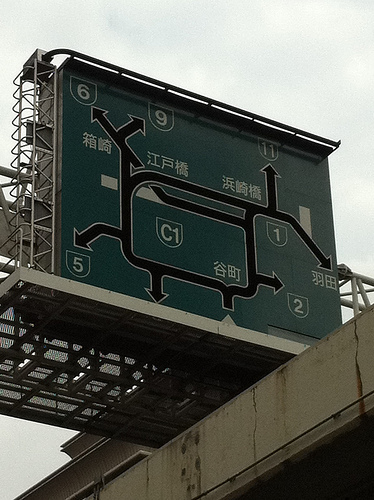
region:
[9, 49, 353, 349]
black structure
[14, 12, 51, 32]
white clouds in blue sky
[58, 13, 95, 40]
white clouds in blue sky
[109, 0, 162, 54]
white clouds in blue sky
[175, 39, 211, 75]
white clouds in blue sky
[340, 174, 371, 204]
white clouds in blue sky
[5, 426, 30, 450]
white clouds in blue sky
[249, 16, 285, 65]
white clouds in blue sky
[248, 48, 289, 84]
white clouds in blue sky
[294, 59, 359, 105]
white clouds in blue sky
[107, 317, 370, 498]
a broken top of a wall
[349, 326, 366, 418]
rust in the crack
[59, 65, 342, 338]
a green traffic sign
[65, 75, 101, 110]
the number 6 on the sign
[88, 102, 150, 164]
arrows pointing to the 6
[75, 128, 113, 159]
characters on the sign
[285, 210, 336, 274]
an arrow pointing down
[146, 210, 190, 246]
C1 on the sign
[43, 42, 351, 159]
a bar across the top of the sign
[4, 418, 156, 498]
a building behind the sign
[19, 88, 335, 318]
large green street sign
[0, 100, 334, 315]
large sign on buildgin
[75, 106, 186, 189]
black arrows on sign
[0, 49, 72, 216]
metal rafters on side of sign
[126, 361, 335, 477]
concrete bridge of sign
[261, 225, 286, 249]
green and white number on sign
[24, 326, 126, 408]
bottom metal grate of sign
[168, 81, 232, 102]
top metal pole of sign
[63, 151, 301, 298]
black arrow map on sign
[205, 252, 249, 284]
foreign writing on sign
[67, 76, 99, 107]
a number on a billboard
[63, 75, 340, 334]
a convoluted street sign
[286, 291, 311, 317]
the number two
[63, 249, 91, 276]
the number five on a street sign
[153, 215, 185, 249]
C1 on a street sign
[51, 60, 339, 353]
a large green street sign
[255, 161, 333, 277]
directional arrows on a street sign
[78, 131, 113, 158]
text in a foreign language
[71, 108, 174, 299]
a row of black lines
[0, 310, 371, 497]
a dirty concrete barrier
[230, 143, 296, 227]
the arrow is pointing up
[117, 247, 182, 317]
the arrow is pointing down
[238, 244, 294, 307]
the arrow is pointing right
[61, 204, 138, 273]
the arrow is pointing left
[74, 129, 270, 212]
the writing is white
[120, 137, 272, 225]
the writing is in another language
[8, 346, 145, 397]
the lights are on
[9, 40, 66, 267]
metal pipes zig zagging up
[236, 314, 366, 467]
cracks in the concrete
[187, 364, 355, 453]
the concrete is beige